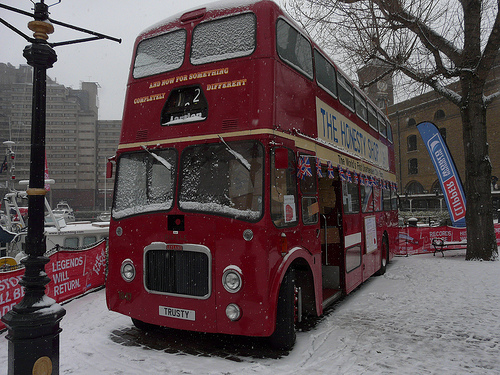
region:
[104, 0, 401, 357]
the bus is red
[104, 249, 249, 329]
the bus has lights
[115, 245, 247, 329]
the buses lights are round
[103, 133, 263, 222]
the bus has snow on the windshield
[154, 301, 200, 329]
the bus has a small white sign on the front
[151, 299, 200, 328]
the sign says TRUSTY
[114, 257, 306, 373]
the tires are black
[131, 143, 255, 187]
the bus has snow on the windshield wipers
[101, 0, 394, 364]
the bus is a double decker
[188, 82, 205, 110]
the bus has the number 2 on it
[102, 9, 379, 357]
A British red double decker bus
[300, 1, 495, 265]
Tree has lost all of its leaves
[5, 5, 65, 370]
Dark black and brass metal street post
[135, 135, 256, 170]
The bus has snow on both wiper blades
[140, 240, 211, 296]
Black radiator with gray metal trim on front of bus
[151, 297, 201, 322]
Front plate on bus says Trusty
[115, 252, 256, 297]
Two large round headlights on bus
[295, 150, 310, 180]
Small British flag on side of bus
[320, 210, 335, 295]
Silver metal grab bar to assist passengers off and on bus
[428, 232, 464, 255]
Wooden bench with snow on it in background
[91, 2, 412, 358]
double-decker bus is red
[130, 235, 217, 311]
vents in front of bus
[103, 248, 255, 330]
three headlights in front of bus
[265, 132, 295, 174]
mirror on right side of bus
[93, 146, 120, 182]
mirror on left side of bus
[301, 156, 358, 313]
door of bus is big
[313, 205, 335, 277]
handle of door of bus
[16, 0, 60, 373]
pole in front of bus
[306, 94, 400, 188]
yellow sign on side of bus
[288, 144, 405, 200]
Britain flags on side of bus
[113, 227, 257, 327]
front of double decker bus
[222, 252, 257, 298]
front headlamp of bus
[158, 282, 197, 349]
front tag of bus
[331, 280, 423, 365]
bus sitting on snow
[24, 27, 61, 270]
black and gold lamp post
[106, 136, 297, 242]
front windshield of bus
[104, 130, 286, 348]
bus is tall and red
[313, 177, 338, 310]
silver rail on red bus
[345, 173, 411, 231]
windows of red bus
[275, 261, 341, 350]
big tire of red bus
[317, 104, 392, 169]
The sign says "The honesty shop"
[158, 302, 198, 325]
The plate reads "TRUSTY"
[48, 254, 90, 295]
The advertisement says "Legends will return"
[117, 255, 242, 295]
The vehicle has two headlights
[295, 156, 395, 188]
The vehicle has British flags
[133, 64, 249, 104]
The vehicle says "And now for something completely different"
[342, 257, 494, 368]
Snow is on the ground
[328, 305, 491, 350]
Footprints are visible in the snow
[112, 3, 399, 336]
The vehicle is red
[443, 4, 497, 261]
A tree is near the vehicle